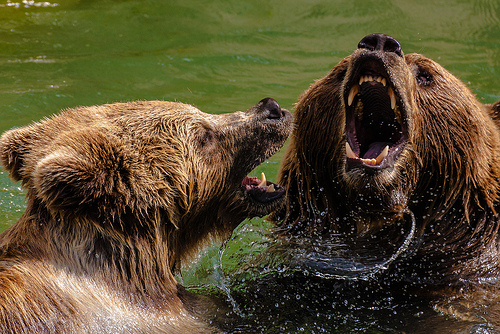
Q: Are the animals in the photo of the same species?
A: Yes, all the animals are bears.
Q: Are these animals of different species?
A: No, all the animals are bears.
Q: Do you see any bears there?
A: Yes, there is a bear.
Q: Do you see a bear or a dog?
A: Yes, there is a bear.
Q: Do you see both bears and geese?
A: No, there is a bear but no geese.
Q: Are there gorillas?
A: No, there are no gorillas.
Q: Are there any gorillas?
A: No, there are no gorillas.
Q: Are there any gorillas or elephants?
A: No, there are no gorillas or elephants.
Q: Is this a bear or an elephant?
A: This is a bear.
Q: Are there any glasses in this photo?
A: No, there are no glasses.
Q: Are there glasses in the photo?
A: No, there are no glasses.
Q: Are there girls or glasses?
A: No, there are no glasses or girls.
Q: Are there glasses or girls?
A: No, there are no glasses or girls.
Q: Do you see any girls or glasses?
A: No, there are no glasses or girls.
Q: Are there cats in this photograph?
A: No, there are no cats.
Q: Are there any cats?
A: No, there are no cats.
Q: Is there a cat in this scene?
A: No, there are no cats.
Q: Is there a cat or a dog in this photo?
A: No, there are no cats or dogs.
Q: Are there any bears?
A: Yes, there is a bear.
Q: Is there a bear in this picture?
A: Yes, there is a bear.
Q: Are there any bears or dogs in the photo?
A: Yes, there is a bear.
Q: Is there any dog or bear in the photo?
A: Yes, there is a bear.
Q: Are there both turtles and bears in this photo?
A: No, there is a bear but no turtles.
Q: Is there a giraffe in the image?
A: No, there are no giraffes.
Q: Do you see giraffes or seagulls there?
A: No, there are no giraffes or seagulls.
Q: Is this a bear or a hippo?
A: This is a bear.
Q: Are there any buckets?
A: No, there are no buckets.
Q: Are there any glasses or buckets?
A: No, there are no buckets or glasses.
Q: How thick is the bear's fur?
A: The fur is thick.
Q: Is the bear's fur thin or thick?
A: The fur is thick.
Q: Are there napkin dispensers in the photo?
A: No, there are no napkin dispensers.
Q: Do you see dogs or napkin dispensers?
A: No, there are no napkin dispensers or dogs.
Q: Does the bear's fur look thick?
A: Yes, the fur is thick.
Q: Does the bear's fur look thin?
A: No, the fur is thick.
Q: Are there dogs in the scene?
A: No, there are no dogs.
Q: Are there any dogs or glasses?
A: No, there are no dogs or glasses.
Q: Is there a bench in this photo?
A: No, there are no benches.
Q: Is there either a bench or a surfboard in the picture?
A: No, there are no benches or surfboards.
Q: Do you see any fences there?
A: No, there are no fences.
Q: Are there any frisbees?
A: No, there are no frisbees.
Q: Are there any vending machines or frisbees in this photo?
A: No, there are no frisbees or vending machines.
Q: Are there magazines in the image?
A: No, there are no magazines.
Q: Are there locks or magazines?
A: No, there are no magazines or locks.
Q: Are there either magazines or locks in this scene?
A: No, there are no magazines or locks.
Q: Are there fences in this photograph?
A: No, there are no fences.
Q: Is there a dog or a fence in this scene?
A: No, there are no fences or dogs.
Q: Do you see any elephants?
A: No, there are no elephants.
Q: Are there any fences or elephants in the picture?
A: No, there are no elephants or fences.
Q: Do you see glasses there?
A: No, there are no glasses.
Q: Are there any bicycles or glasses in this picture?
A: No, there are no glasses or bicycles.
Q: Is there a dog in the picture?
A: No, there are no dogs.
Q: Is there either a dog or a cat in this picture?
A: No, there are no dogs or cats.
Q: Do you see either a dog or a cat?
A: No, there are no dogs or cats.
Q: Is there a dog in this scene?
A: No, there are no dogs.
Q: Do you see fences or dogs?
A: No, there are no dogs or fences.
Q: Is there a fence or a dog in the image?
A: No, there are no dogs or fences.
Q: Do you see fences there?
A: No, there are no fences.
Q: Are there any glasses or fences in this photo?
A: No, there are no fences or glasses.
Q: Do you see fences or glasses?
A: No, there are no fences or glasses.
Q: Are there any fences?
A: No, there are no fences.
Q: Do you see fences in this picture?
A: No, there are no fences.